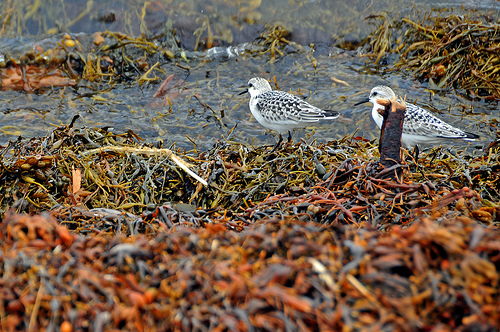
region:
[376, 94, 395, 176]
a broken tree branch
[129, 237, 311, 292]
wet leaves on the ground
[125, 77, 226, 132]
water soaking vegetation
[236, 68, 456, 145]
two black and white birds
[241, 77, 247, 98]
a long black beak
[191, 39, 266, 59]
a snake slithering in the water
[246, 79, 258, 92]
a round black eye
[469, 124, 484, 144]
black tail feathers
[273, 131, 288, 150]
two thin black bird legs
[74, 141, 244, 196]
wet seaweed near the birds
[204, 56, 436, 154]
two birds on the ground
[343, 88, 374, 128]
beak of the bird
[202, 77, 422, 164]
two birds next to each other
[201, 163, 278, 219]
stuff on the ground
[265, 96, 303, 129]
feathers of the bird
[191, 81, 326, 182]
light and dark colored bird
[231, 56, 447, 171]
birds looking to the left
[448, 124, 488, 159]
tail feather of the bird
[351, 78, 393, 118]
head of the bird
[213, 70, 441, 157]
birds standing near water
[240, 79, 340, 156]
bird is black and white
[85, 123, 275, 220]
brown twigs on ground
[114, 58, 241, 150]
standing water near two birds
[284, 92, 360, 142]
bird has black tail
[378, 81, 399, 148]
broken stick near bird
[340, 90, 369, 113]
bird has black beak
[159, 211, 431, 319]
orange plants in front of bird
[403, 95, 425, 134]
bird's back is spotted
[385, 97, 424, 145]
bird's back is black and white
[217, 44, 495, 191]
Two birds are standing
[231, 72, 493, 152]
Two black and white birds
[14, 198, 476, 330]
orange and brown seaweed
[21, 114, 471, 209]
Green and black seaweed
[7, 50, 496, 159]
Water by the birds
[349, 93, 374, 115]
Black beak of bird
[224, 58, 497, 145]
One bird behind the other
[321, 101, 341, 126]
Black tips of tail feathers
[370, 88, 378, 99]
Small eye of bird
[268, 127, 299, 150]
Small black legs of bird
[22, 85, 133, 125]
There is some water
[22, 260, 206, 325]
The leaves are red and brown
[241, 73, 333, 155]
A bird is standing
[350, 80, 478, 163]
The bird is white and black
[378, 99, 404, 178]
There is a tree stump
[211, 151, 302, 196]
The grass is dying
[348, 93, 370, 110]
Bird has a black beak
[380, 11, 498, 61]
The reeds are green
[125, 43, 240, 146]
Reeds are in the water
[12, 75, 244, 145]
The water is shallow